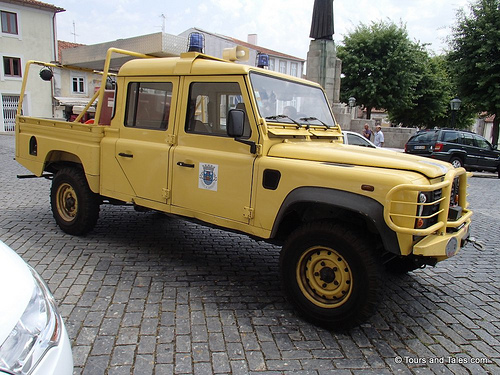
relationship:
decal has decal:
[198, 162, 216, 191] [198, 162, 219, 192]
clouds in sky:
[389, 9, 451, 43] [183, 5, 297, 30]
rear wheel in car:
[50, 171, 127, 238] [13, 31, 486, 334]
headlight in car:
[407, 185, 430, 235] [6, 32, 484, 337]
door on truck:
[176, 75, 272, 220] [14, 30, 486, 333]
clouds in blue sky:
[86, 2, 130, 26] [1, 1, 499, 79]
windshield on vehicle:
[246, 69, 336, 128] [13, 50, 469, 317]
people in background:
[352, 118, 387, 152] [137, 7, 306, 41]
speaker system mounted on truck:
[220, 41, 251, 67] [14, 30, 486, 333]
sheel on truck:
[278, 220, 386, 332] [16, 34, 346, 293]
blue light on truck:
[187, 31, 206, 49] [14, 30, 486, 333]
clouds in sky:
[122, 1, 214, 28] [38, 0, 480, 78]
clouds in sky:
[86, 2, 138, 27] [38, 0, 480, 65]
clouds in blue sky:
[86, 2, 130, 26] [68, 0, 454, 35]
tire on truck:
[279, 221, 388, 333] [20, 40, 472, 312]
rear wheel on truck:
[49, 166, 103, 236] [20, 40, 472, 312]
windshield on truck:
[246, 69, 336, 128] [14, 30, 486, 333]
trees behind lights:
[337, 22, 459, 128] [343, 86, 360, 116]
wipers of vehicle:
[265, 110, 327, 127] [13, 50, 469, 317]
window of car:
[181, 72, 256, 136] [13, 31, 486, 334]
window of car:
[119, 77, 174, 127] [13, 31, 486, 334]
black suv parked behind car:
[410, 128, 498, 179] [13, 31, 486, 334]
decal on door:
[198, 162, 219, 192] [170, 74, 262, 226]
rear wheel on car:
[49, 166, 103, 236] [13, 31, 486, 334]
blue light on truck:
[183, 29, 206, 49] [101, 76, 389, 249]